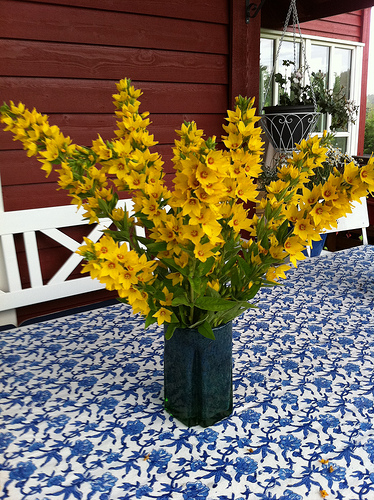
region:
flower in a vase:
[320, 149, 361, 256]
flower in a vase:
[280, 138, 309, 202]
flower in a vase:
[237, 96, 265, 202]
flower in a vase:
[103, 75, 159, 191]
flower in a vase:
[16, 102, 106, 195]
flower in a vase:
[77, 235, 158, 305]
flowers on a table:
[11, 63, 367, 429]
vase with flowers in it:
[8, 112, 366, 437]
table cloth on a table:
[55, 342, 130, 463]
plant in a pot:
[315, 64, 356, 124]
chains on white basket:
[262, 0, 314, 148]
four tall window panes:
[261, 35, 352, 135]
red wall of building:
[4, 4, 258, 322]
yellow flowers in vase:
[2, 78, 367, 425]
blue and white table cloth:
[0, 243, 372, 498]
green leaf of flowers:
[190, 296, 238, 311]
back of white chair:
[304, 193, 369, 256]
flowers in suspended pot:
[265, 60, 356, 142]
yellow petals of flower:
[224, 105, 242, 121]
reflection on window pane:
[330, 47, 349, 131]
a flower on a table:
[5, 85, 367, 425]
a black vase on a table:
[156, 319, 251, 421]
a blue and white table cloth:
[232, 310, 360, 469]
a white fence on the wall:
[3, 206, 76, 303]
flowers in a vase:
[20, 121, 365, 331]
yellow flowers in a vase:
[0, 118, 373, 337]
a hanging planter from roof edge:
[243, 9, 327, 158]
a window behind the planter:
[267, 23, 366, 199]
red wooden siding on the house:
[35, 18, 236, 92]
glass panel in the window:
[331, 52, 358, 122]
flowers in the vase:
[143, 119, 278, 279]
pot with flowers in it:
[163, 328, 241, 414]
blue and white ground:
[280, 376, 327, 420]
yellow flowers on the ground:
[305, 458, 345, 499]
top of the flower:
[109, 68, 149, 109]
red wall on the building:
[52, 24, 97, 73]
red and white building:
[24, 201, 53, 268]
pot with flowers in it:
[266, 70, 332, 136]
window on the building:
[313, 28, 362, 75]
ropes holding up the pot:
[272, 12, 311, 39]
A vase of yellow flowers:
[1, 96, 369, 420]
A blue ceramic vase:
[161, 318, 236, 423]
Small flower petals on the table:
[317, 450, 335, 498]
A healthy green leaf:
[191, 294, 234, 312]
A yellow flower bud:
[192, 242, 214, 262]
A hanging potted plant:
[256, 0, 352, 149]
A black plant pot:
[263, 102, 318, 152]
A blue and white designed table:
[1, 288, 372, 497]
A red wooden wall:
[0, 15, 247, 207]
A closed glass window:
[256, 33, 361, 177]